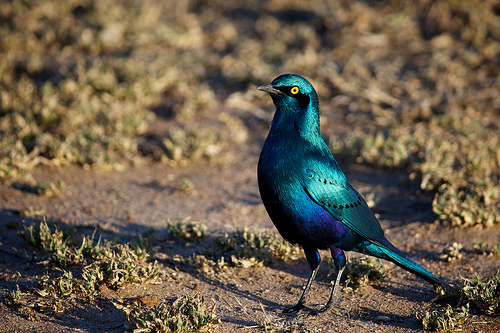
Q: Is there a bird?
A: Yes, there is a bird.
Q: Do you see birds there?
A: Yes, there is a bird.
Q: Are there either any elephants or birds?
A: Yes, there is a bird.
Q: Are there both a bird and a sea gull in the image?
A: No, there is a bird but no seagulls.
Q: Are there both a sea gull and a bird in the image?
A: No, there is a bird but no seagulls.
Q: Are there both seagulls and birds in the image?
A: No, there is a bird but no seagulls.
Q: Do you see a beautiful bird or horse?
A: Yes, there is a beautiful bird.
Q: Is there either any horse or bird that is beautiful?
A: Yes, the bird is beautiful.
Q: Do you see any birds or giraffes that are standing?
A: Yes, the bird is standing.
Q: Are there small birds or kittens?
A: Yes, there is a small bird.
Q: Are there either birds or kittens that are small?
A: Yes, the bird is small.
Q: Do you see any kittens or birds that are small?
A: Yes, the bird is small.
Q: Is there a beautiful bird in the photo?
A: Yes, there is a beautiful bird.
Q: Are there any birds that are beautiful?
A: Yes, there is a bird that is beautiful.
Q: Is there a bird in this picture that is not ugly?
A: Yes, there is an beautiful bird.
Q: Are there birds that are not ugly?
A: Yes, there is an beautiful bird.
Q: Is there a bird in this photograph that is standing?
A: Yes, there is a bird that is standing.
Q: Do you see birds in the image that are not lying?
A: Yes, there is a bird that is standing .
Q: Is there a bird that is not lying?
A: Yes, there is a bird that is standing.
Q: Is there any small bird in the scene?
A: Yes, there is a small bird.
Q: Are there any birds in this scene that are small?
A: Yes, there is a bird that is small.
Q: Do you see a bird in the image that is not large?
A: Yes, there is a small bird.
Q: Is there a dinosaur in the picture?
A: No, there are no dinosaurs.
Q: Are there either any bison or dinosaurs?
A: No, there are no dinosaurs or bison.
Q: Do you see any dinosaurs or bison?
A: No, there are no dinosaurs or bison.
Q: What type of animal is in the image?
A: The animal is a bird.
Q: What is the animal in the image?
A: The animal is a bird.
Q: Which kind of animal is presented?
A: The animal is a bird.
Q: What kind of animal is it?
A: The animal is a bird.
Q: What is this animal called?
A: This is a bird.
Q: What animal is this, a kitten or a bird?
A: This is a bird.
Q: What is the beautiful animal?
A: The animal is a bird.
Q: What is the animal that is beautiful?
A: The animal is a bird.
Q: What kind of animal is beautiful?
A: The animal is a bird.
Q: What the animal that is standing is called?
A: The animal is a bird.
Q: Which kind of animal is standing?
A: The animal is a bird.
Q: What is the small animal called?
A: The animal is a bird.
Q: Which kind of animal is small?
A: The animal is a bird.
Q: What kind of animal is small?
A: The animal is a bird.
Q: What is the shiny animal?
A: The animal is a bird.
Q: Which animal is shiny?
A: The animal is a bird.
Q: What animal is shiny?
A: The animal is a bird.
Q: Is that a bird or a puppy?
A: That is a bird.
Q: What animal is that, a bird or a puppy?
A: That is a bird.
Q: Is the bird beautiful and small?
A: Yes, the bird is beautiful and small.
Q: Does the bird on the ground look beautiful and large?
A: No, the bird is beautiful but small.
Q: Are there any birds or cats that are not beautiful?
A: No, there is a bird but it is beautiful.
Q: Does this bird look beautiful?
A: Yes, the bird is beautiful.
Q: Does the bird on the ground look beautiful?
A: Yes, the bird is beautiful.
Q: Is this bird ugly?
A: No, the bird is beautiful.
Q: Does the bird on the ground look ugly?
A: No, the bird is beautiful.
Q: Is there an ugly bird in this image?
A: No, there is a bird but it is beautiful.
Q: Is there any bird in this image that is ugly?
A: No, there is a bird but it is beautiful.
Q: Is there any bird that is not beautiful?
A: No, there is a bird but it is beautiful.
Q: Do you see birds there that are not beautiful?
A: No, there is a bird but it is beautiful.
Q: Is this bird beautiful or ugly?
A: The bird is beautiful.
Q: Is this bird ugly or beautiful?
A: The bird is beautiful.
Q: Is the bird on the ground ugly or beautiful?
A: The bird is beautiful.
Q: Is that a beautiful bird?
A: Yes, that is a beautiful bird.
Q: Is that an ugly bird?
A: No, that is a beautiful bird.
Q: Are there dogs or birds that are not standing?
A: No, there is a bird but it is standing.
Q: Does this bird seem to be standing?
A: Yes, the bird is standing.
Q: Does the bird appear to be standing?
A: Yes, the bird is standing.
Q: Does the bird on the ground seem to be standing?
A: Yes, the bird is standing.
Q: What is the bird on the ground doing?
A: The bird is standing.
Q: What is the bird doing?
A: The bird is standing.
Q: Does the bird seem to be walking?
A: No, the bird is standing.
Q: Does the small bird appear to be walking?
A: No, the bird is standing.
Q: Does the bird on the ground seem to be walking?
A: No, the bird is standing.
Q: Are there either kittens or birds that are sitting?
A: No, there is a bird but it is standing.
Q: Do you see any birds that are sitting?
A: No, there is a bird but it is standing.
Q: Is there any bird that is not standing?
A: No, there is a bird but it is standing.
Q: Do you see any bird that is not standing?
A: No, there is a bird but it is standing.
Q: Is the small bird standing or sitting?
A: The bird is standing.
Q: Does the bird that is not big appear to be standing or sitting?
A: The bird is standing.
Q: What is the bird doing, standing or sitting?
A: The bird is standing.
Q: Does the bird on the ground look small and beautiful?
A: Yes, the bird is small and beautiful.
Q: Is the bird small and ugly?
A: No, the bird is small but beautiful.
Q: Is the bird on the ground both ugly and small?
A: No, the bird is small but beautiful.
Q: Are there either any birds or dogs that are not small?
A: No, there is a bird but it is small.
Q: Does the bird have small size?
A: Yes, the bird is small.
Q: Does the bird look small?
A: Yes, the bird is small.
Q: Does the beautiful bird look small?
A: Yes, the bird is small.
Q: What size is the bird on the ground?
A: The bird is small.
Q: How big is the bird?
A: The bird is small.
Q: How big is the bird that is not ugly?
A: The bird is small.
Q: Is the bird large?
A: No, the bird is small.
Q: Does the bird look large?
A: No, the bird is small.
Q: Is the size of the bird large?
A: No, the bird is small.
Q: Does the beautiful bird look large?
A: No, the bird is small.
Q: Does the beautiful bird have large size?
A: No, the bird is small.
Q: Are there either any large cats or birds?
A: No, there is a bird but it is small.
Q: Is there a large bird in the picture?
A: No, there is a bird but it is small.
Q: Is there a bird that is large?
A: No, there is a bird but it is small.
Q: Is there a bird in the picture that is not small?
A: No, there is a bird but it is small.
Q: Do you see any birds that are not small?
A: No, there is a bird but it is small.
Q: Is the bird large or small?
A: The bird is small.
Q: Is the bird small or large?
A: The bird is small.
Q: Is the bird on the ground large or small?
A: The bird is small.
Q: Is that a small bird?
A: Yes, that is a small bird.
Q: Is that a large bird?
A: No, that is a small bird.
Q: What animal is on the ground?
A: The bird is on the ground.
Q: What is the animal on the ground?
A: The animal is a bird.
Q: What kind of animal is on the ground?
A: The animal is a bird.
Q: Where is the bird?
A: The bird is on the ground.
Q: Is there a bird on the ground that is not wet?
A: Yes, there is a bird on the ground.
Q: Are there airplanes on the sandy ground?
A: No, there is a bird on the ground.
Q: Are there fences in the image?
A: No, there are no fences.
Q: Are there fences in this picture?
A: No, there are no fences.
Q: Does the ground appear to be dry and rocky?
A: No, the ground is dry but sandy.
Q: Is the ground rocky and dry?
A: No, the ground is dry but sandy.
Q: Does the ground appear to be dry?
A: Yes, the ground is dry.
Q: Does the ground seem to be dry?
A: Yes, the ground is dry.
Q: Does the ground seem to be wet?
A: No, the ground is dry.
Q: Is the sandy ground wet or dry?
A: The ground is dry.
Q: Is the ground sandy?
A: Yes, the ground is sandy.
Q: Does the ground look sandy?
A: Yes, the ground is sandy.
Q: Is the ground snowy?
A: No, the ground is sandy.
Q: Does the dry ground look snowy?
A: No, the ground is sandy.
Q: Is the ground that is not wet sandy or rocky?
A: The ground is sandy.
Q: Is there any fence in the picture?
A: No, there are no fences.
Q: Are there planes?
A: No, there are no planes.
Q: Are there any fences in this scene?
A: No, there are no fences.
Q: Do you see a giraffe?
A: No, there are no giraffes.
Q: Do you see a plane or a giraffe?
A: No, there are no giraffes or airplanes.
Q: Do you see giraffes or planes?
A: No, there are no giraffes or planes.